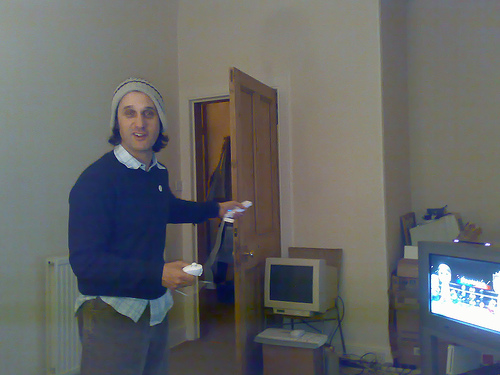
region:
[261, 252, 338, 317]
old style heavy CRT tan monitor powered off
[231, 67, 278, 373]
ajar light wooden door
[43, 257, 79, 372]
white metal radiator attached to wall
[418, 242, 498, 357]
powered on television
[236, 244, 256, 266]
brass colored door knob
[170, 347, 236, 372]
worn brown carpeting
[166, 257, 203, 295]
wii joystick grasped in hand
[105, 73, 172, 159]
Caucasian male face looking towards camera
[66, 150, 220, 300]
dark blue long sleeved shirt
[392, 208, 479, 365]
stack of boxes and various clutter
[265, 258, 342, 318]
Light cream computer monitor.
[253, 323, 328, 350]
Computer keyboard and mouse.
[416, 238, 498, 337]
Grey television on stand.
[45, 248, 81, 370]
White heated near wall.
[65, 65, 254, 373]
Man with game controllers in his hand.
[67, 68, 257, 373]
Man wearing beige hat with black stripe.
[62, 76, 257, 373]
Man playing video game.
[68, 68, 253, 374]
Man wearing dark colored sweater.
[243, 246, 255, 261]
Brass colored door knob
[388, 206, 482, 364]
Stack of cardboard boxes in a corner.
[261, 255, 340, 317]
a computer monitor that is not turned on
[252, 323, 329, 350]
a keyboard sitting in front of the monitor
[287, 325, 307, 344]
a mouse sitting on top of a keyboard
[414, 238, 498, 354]
a television that is turned on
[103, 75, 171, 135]
a hat on the man's head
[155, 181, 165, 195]
an emblem on the man's shirt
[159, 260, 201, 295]
the man's right hand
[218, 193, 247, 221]
the man's left hand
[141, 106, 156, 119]
the man's left eye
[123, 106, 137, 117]
the man's right eye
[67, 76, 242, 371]
man in blue sweater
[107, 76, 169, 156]
face of man in hat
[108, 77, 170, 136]
hat on mans head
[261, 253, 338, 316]
computer monitor on chair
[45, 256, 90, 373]
white radiator on the wall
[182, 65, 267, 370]
door being held open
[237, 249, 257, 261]
knob on brown door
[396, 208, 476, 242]
things piled on the back wall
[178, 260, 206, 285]
wii controller in mans hand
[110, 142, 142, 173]
white collar of shirt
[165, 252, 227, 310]
white remote in man's hand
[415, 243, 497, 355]
game in the tv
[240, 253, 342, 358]
old computure and keyboard on table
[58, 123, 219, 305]
blue jacket on young man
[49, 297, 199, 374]
young man wearing brown pants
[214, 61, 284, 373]
one brown door next to man's hand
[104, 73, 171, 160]
one light tan beanie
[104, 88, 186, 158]
man wearing tanish beanie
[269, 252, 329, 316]
black computure screen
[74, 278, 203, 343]
light blue shirt under dark blue shirt